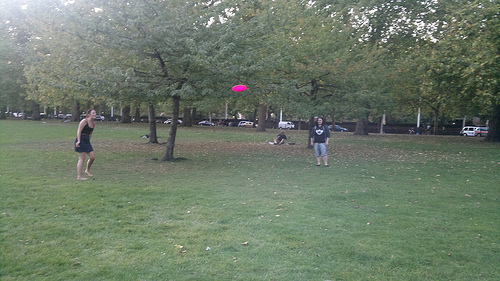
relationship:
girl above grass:
[65, 101, 105, 185] [4, 120, 500, 278]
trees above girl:
[23, 1, 496, 151] [65, 101, 105, 185]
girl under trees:
[65, 101, 105, 185] [23, 1, 496, 151]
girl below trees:
[65, 101, 105, 185] [23, 1, 496, 151]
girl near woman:
[65, 101, 105, 185] [305, 114, 340, 169]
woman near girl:
[305, 114, 340, 169] [65, 101, 105, 185]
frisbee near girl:
[231, 82, 249, 95] [65, 101, 105, 185]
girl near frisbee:
[65, 101, 105, 185] [231, 82, 249, 95]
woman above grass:
[305, 114, 340, 169] [4, 120, 500, 278]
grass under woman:
[4, 120, 500, 278] [305, 114, 340, 169]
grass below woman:
[4, 120, 500, 278] [305, 114, 340, 169]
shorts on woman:
[310, 140, 328, 159] [305, 114, 340, 169]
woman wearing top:
[71, 104, 97, 179] [80, 112, 96, 140]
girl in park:
[71, 107, 101, 180] [7, 27, 497, 274]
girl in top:
[71, 107, 101, 180] [72, 115, 95, 145]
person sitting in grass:
[263, 123, 285, 150] [4, 120, 500, 278]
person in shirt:
[74, 103, 99, 183] [72, 113, 97, 143]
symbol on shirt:
[311, 127, 322, 136] [309, 123, 329, 141]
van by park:
[274, 118, 294, 129] [7, 27, 497, 274]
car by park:
[201, 119, 217, 126] [2, 3, 490, 274]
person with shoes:
[309, 116, 330, 166] [316, 158, 328, 169]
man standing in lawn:
[75, 105, 97, 184] [2, 136, 497, 278]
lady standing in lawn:
[308, 114, 330, 162] [2, 136, 497, 278]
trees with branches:
[23, 1, 496, 151] [150, 40, 194, 100]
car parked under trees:
[463, 116, 489, 140] [23, 1, 496, 151]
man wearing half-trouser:
[309, 107, 334, 165] [312, 140, 330, 159]